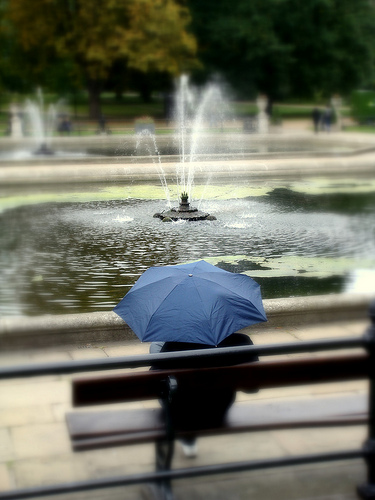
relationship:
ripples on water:
[8, 172, 373, 331] [6, 186, 366, 298]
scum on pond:
[102, 181, 255, 200] [7, 199, 373, 293]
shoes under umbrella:
[173, 437, 201, 458] [107, 263, 276, 353]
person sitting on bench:
[147, 332, 258, 457] [61, 353, 371, 453]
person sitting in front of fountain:
[147, 332, 258, 457] [0, 168, 374, 315]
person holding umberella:
[147, 332, 258, 457] [111, 257, 269, 348]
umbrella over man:
[110, 260, 266, 346] [147, 332, 259, 457]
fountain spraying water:
[152, 191, 217, 221] [0, 71, 373, 315]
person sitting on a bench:
[147, 332, 258, 457] [65, 350, 369, 498]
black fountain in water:
[157, 187, 213, 219] [0, 170, 375, 315]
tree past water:
[8, 7, 207, 107] [1, 179, 363, 316]